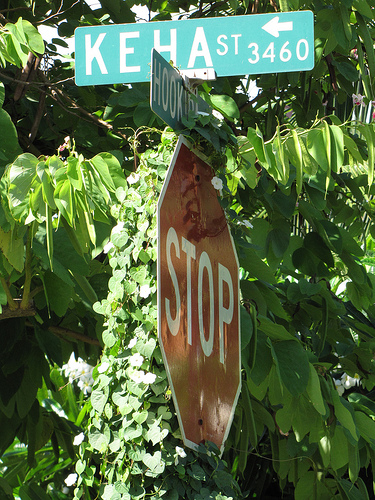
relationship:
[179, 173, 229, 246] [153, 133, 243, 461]
graffiti on stop sign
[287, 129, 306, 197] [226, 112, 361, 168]
pod on a limb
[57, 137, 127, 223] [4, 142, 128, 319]
pods are in a group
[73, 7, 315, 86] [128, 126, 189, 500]
street sign attached to a pole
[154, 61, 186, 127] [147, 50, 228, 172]
hook appears on a street sign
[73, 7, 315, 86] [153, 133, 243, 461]
street sign over stop sign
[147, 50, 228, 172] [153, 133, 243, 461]
street sign over stop sign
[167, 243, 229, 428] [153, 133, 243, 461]
reflection appears on stop sign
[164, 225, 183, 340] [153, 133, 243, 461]
s appears on stop sign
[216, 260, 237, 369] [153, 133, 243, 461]
p appears on stop sign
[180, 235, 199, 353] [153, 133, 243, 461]
t appears on stop sign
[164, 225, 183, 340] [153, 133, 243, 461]
s on stop sign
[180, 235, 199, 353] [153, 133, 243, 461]
t on stop sign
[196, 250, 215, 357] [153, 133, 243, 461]
o on stop sign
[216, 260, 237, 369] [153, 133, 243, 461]
p on stop sign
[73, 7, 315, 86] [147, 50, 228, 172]
street sign over another street sign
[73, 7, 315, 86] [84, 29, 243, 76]
street sign says keha st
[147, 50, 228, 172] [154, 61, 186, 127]
sign says hook st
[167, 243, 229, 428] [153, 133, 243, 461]
reflection on stop sign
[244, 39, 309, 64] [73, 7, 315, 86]
numbers appear on street sign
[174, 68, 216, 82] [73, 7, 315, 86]
bracket holding up street sign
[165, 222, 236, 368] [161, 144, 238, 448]
stop written on red background